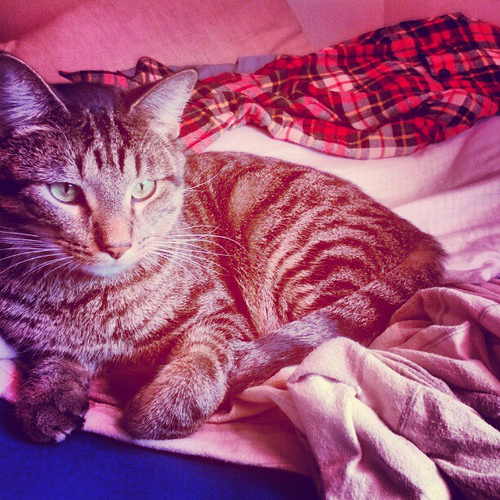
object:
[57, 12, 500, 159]
blanket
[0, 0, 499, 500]
couch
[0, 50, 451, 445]
cat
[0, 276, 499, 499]
blanket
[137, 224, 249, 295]
whiskers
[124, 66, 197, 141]
ear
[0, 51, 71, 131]
ear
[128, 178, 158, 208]
eyes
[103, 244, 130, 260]
nose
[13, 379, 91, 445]
paw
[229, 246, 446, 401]
tail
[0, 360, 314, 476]
blanket